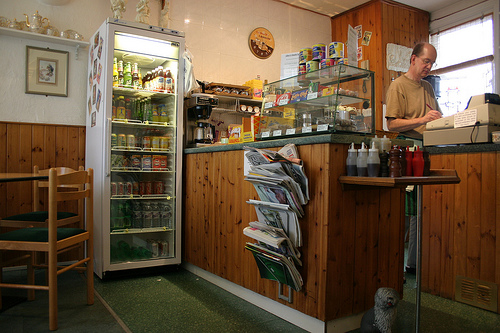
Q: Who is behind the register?
A: A man.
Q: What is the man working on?
A: A cash register.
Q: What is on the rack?
A: Newspapers.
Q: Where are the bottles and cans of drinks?
A: In the beverage cooler.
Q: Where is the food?
A: In the case on the counter.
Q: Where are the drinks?
A: Cooler.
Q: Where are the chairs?
A: At the table.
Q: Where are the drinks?
A: Refrigerator.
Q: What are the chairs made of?
A: Wood.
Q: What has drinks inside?
A: Cooler.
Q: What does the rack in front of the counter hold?
A: Newspapers.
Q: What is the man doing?
A: Writing.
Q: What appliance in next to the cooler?
A: Coffee pot.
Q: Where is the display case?
A: On the counter.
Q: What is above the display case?
A: Cans.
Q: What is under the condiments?
A: Dog.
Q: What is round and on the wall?
A: Clock.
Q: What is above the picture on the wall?
A: Tea set.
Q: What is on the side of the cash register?
A: Paper.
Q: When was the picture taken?
A: Daytime.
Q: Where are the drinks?
A: In the cooler.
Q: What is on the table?
A: Bottles.